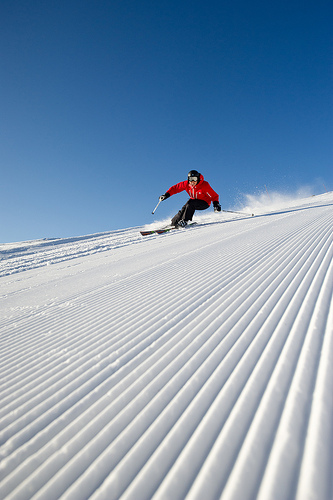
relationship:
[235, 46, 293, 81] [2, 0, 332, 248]
clouds in blue sky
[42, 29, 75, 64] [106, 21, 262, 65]
clouds in blue sky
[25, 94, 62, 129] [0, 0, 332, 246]
clouds in blue sky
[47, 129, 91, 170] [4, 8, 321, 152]
clouds in sky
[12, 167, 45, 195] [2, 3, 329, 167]
clouds in sky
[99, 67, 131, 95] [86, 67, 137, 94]
clouds in sky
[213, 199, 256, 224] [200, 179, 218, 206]
pole on left hand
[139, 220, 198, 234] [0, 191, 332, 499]
skis on snow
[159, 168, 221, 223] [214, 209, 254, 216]
skier holds pole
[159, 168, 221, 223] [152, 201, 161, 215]
skier holds pole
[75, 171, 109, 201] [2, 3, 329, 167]
clouds in sky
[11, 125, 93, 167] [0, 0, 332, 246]
clouds in blue sky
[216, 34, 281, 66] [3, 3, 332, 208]
clouds in sky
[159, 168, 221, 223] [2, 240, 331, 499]
skier down slope